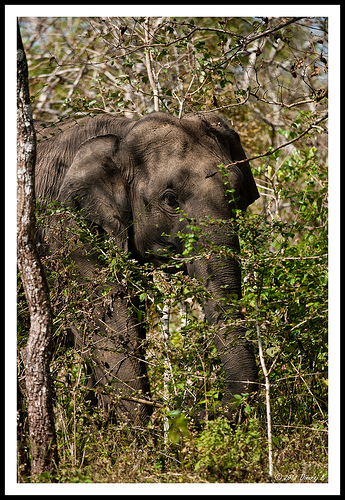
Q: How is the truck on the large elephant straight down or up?
A: Down.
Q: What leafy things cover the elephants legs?
A: Branches.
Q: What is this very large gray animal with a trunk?
A: Elephant.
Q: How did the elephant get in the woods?
A: Walked.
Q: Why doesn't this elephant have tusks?
A: It's female.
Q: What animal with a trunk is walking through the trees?
A: Elephant.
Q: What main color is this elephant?
A: Gray.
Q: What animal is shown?
A: An elephant.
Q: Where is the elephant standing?
A: In trees.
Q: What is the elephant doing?
A: Standing.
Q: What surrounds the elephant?
A: Trees.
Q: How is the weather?
A: Sunny.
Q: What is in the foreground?
A: Tree trunk.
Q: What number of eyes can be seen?
A: One.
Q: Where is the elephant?
A: Standing behind the trees and bushes.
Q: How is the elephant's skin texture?
A: Thick and wrinkled.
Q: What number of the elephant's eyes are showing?
A: One.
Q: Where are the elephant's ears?
A: On the side of the elephant's head.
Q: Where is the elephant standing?
A: On the ground.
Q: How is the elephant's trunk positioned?
A: Straight down.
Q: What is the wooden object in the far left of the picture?
A: A small tree trunk.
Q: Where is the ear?
A: On the elephant.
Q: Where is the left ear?
A: On the elephant.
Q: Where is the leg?
A: On the elephant.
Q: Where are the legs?
A: In the elephant.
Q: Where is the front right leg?
A: On the elephant.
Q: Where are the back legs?
A: On the elephant.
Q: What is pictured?
A: An elephant.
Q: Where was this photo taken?
A: In the elephant's habitat.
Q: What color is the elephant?
A: Grey.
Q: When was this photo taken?
A: During the day.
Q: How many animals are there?
A: Just 1.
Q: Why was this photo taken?
A: To capture the elephant.